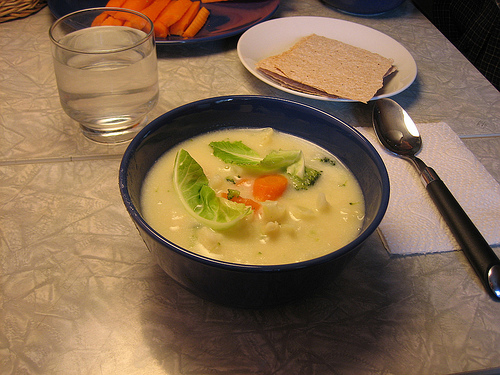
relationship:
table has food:
[52, 262, 172, 354] [144, 115, 364, 260]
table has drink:
[52, 262, 172, 354] [46, 10, 157, 121]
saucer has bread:
[260, 20, 300, 42] [293, 57, 370, 89]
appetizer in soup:
[169, 147, 256, 232] [227, 122, 331, 229]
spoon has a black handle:
[372, 97, 484, 261] [430, 184, 484, 267]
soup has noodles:
[164, 137, 324, 242] [265, 206, 301, 234]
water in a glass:
[52, 22, 158, 133] [101, 9, 142, 30]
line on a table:
[84, 270, 122, 279] [40, 247, 151, 337]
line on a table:
[87, 228, 124, 244] [56, 209, 129, 304]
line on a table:
[97, 264, 119, 281] [48, 242, 145, 343]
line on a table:
[78, 252, 127, 264] [53, 255, 144, 325]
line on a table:
[78, 245, 127, 265] [14, 243, 153, 334]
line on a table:
[10, 265, 51, 277] [38, 271, 153, 338]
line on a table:
[172, 349, 187, 372] [44, 267, 147, 328]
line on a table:
[11, 150, 62, 170] [23, 231, 139, 342]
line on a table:
[78, 252, 127, 264] [43, 264, 174, 361]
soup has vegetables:
[145, 123, 365, 264] [174, 150, 321, 239]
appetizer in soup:
[169, 147, 256, 232] [145, 112, 385, 272]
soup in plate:
[145, 123, 365, 264] [114, 91, 392, 308]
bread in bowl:
[253, 29, 399, 108] [236, 14, 422, 104]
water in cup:
[52, 22, 157, 119] [47, 6, 159, 152]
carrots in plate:
[87, 0, 214, 45] [46, 3, 283, 50]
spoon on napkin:
[372, 97, 484, 261] [346, 120, 484, 256]